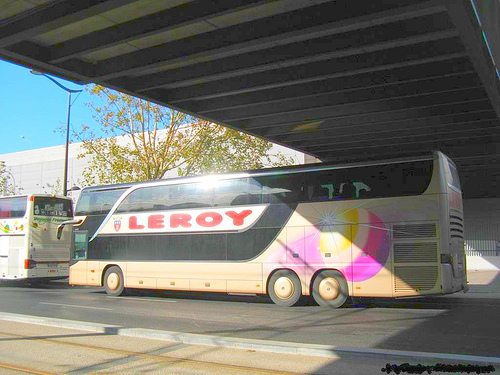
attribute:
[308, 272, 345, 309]
wheel — bus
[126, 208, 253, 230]
logo — bus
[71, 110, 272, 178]
branches — tree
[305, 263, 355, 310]
wheel — bus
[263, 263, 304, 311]
wheel — bus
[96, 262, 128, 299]
wheel — bus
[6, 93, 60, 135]
sky — clear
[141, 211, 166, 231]
letter — bus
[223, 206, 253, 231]
letter — bus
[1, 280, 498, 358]
street — grey, paved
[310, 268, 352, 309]
tire — bus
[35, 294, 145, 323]
line — white